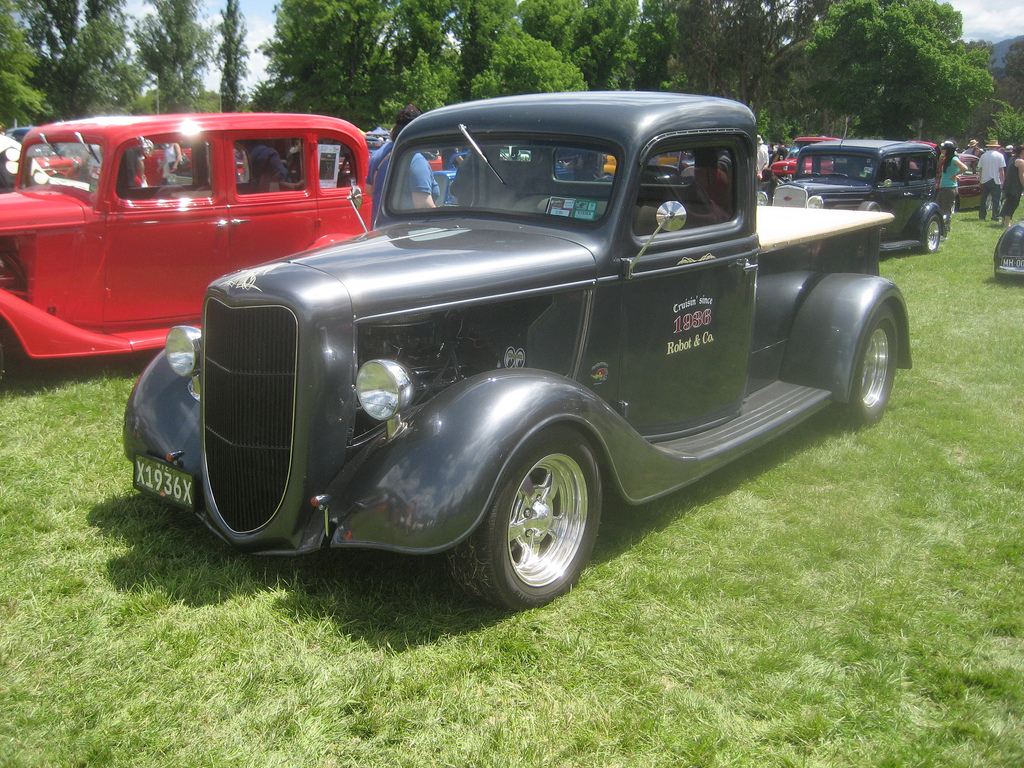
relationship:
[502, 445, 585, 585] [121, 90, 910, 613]
rim on a black truck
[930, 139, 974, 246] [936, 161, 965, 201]
person wearing a blue shirt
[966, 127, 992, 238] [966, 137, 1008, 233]
man wearing a man hat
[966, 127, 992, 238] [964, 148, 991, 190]
man wearing a shirt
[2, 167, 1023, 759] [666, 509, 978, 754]
grass on ground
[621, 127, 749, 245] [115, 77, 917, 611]
open window on black truck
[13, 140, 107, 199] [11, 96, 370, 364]
windshield on a red truck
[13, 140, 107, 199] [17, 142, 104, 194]
windshield with windshield